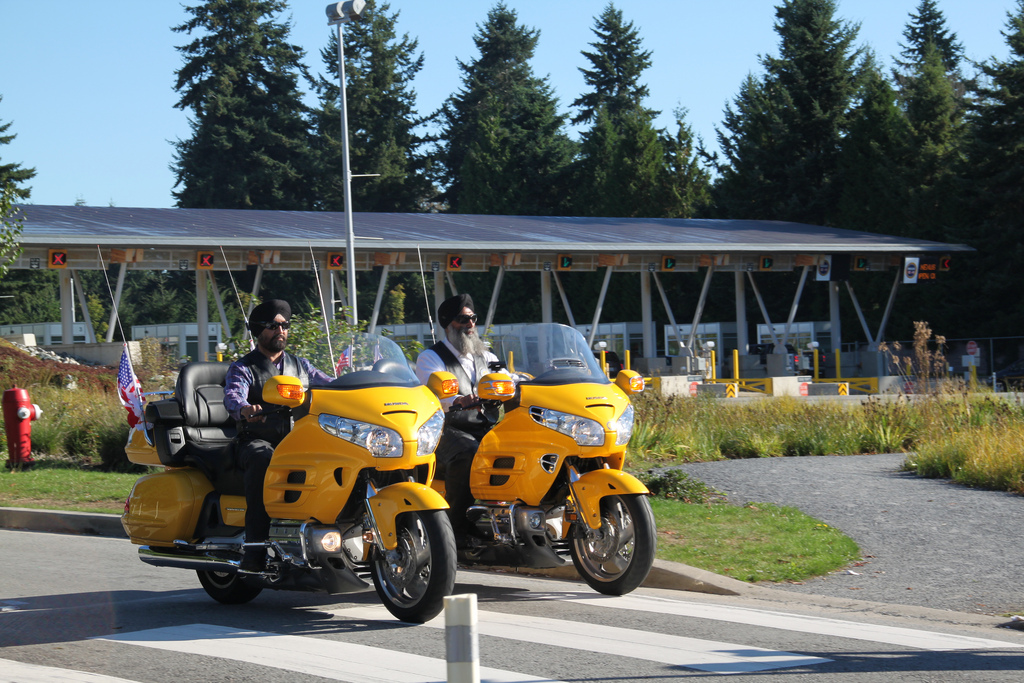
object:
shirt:
[217, 349, 326, 439]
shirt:
[410, 342, 520, 421]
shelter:
[0, 206, 966, 396]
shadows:
[0, 566, 480, 645]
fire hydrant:
[0, 382, 43, 469]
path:
[676, 443, 1023, 610]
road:
[0, 509, 1022, 680]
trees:
[167, 0, 1019, 368]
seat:
[172, 358, 237, 459]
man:
[225, 294, 331, 575]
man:
[411, 289, 528, 541]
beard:
[446, 327, 485, 353]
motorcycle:
[430, 320, 665, 597]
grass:
[2, 465, 126, 509]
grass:
[654, 392, 1019, 573]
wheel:
[362, 482, 461, 623]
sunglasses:
[265, 320, 292, 329]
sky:
[0, 0, 1016, 196]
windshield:
[476, 320, 597, 371]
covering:
[0, 210, 931, 273]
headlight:
[318, 416, 405, 456]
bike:
[120, 359, 459, 617]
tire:
[362, 483, 460, 631]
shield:
[308, 330, 415, 390]